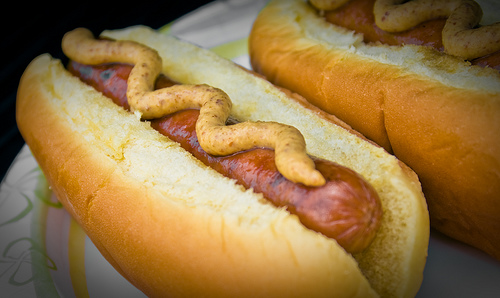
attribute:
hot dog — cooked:
[15, 23, 434, 298]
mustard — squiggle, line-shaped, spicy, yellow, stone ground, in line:
[61, 25, 328, 187]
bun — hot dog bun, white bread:
[16, 25, 431, 297]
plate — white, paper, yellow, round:
[3, 2, 497, 297]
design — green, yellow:
[0, 25, 252, 297]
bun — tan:
[248, 1, 498, 259]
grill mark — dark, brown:
[77, 63, 115, 82]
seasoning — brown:
[89, 37, 306, 176]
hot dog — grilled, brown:
[68, 38, 384, 255]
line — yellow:
[61, 40, 253, 298]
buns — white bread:
[14, 1, 500, 297]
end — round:
[329, 170, 382, 251]